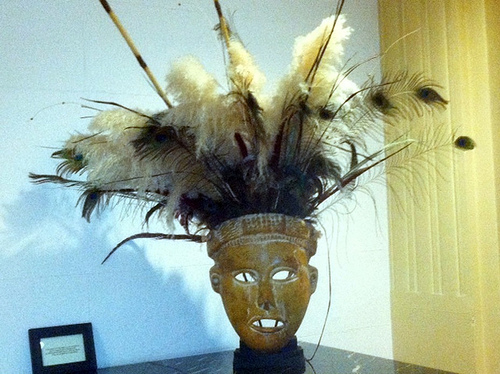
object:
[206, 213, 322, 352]
sculpture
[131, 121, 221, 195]
feathers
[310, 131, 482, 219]
feathers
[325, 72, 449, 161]
feathers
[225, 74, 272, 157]
feathers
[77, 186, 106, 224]
feathers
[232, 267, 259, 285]
eyehole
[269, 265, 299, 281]
eyehole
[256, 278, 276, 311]
nose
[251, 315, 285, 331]
mouthhole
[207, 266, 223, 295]
ear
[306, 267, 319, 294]
ear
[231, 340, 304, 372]
stand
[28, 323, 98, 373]
sign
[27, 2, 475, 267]
headdress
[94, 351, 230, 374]
table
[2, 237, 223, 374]
shadow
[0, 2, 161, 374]
wall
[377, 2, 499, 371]
wall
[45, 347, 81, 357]
letters